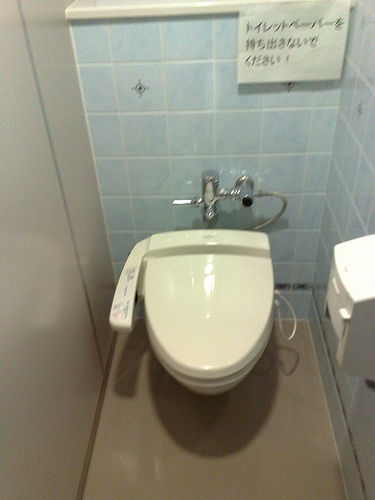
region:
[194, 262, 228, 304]
reflection of light on the toilet seat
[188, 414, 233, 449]
a dark shadow under the toilet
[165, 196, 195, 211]
the toilet handle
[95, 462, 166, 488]
the floor is brown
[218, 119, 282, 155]
the tile on the wall is blue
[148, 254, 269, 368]
the seat is down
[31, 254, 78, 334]
reflection on the wall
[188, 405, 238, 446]
a shadow on the floor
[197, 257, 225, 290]
light on the toilet seat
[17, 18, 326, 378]
this is inside a bathroom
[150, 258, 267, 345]
this is a toilet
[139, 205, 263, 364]
the toilet is white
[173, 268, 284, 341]
the toilet is shiny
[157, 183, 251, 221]
the handle is made of metal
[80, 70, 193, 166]
the tiles are light blue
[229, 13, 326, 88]
the writing is in japanese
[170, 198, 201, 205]
A silver handle on a toilet.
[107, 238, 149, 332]
White controls on a toilet side.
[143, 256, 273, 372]
White toilet lid seat.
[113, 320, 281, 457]
Shadow of a toilet on the floor.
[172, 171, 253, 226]
Hard metal silver hardware behind the toilet.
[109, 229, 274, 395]
A white toilet with controls.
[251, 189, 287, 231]
Grey toilet hose.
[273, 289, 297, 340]
Grey cord on the right side of the toilet.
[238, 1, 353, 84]
Paper with black Chinese writing on it.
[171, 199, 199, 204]
A shiny silver flusher handle.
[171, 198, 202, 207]
The flush handle on the toilet.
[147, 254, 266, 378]
The lid of the toilet.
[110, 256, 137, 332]
The armrest of the toilet.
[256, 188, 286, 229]
The pipe above the toilet.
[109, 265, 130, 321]
The markings on the toilet's armrest.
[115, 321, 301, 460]
The shadow of the toilet on the floor.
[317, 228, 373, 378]
The toilet paper container on the right wall.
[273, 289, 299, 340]
The tube on the right side of the toilet.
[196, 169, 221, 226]
The silver pipe the flush handle is mounted to.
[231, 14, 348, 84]
Foreign writing on the wall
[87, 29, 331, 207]
Blue tile and white grout on the wall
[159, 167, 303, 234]
Chrome colored Toilet piping